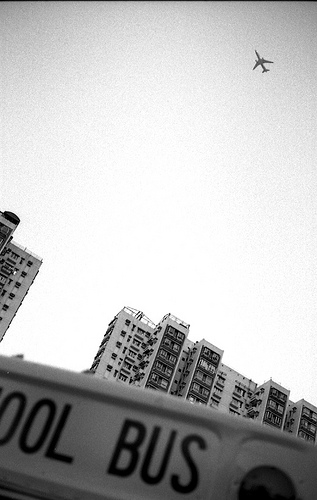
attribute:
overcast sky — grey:
[3, 3, 315, 251]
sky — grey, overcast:
[1, 4, 316, 408]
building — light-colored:
[1, 209, 44, 343]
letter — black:
[2, 383, 226, 496]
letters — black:
[1, 382, 212, 493]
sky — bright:
[55, 70, 210, 185]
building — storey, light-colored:
[89, 304, 316, 441]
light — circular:
[231, 458, 306, 498]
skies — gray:
[65, 66, 218, 197]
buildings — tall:
[81, 296, 314, 438]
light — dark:
[228, 456, 305, 497]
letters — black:
[103, 412, 203, 494]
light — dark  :
[234, 461, 293, 493]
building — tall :
[0, 205, 307, 428]